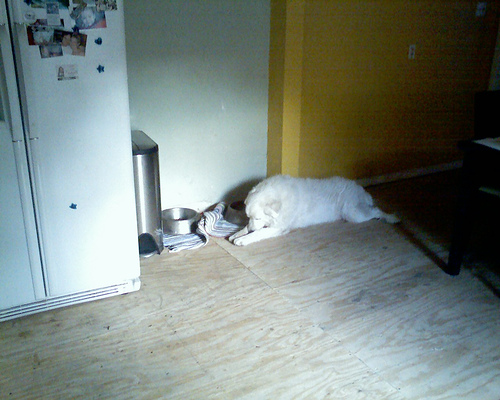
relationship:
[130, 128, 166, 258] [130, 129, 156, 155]
trash can has a lid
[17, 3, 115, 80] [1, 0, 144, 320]
pictures on refrigerator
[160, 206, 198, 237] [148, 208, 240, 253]
bowl on rug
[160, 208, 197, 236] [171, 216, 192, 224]
bowl with food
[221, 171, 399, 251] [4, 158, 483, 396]
dog on floor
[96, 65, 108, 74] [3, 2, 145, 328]
magnet on fridge